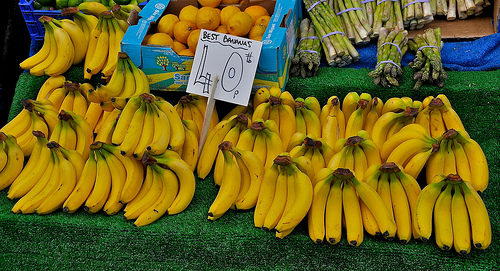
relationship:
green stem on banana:
[457, 180, 471, 194] [458, 180, 491, 250]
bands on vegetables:
[325, 29, 344, 35] [304, 4, 441, 83]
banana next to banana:
[248, 165, 293, 228] [248, 165, 273, 226]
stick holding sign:
[192, 77, 220, 157] [182, 26, 269, 111]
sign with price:
[182, 26, 269, 111] [195, 43, 242, 98]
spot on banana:
[152, 207, 159, 212] [134, 160, 178, 226]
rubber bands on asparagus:
[377, 41, 401, 50] [284, 0, 484, 85]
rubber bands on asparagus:
[372, 57, 404, 72] [284, 0, 484, 85]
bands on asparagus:
[321, 31, 346, 43] [284, 0, 484, 85]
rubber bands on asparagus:
[330, 7, 358, 15] [284, 0, 484, 85]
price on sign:
[199, 43, 243, 101] [189, 27, 269, 122]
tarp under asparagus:
[321, 31, 498, 71] [411, 26, 446, 88]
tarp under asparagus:
[321, 31, 498, 71] [369, 25, 409, 85]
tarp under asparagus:
[321, 31, 498, 71] [302, 0, 359, 68]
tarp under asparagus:
[321, 31, 498, 71] [290, 16, 320, 75]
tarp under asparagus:
[321, 31, 498, 71] [334, 0, 373, 43]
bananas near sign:
[2, 50, 192, 231] [182, 26, 269, 111]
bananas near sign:
[221, 82, 493, 254] [188, 23, 257, 106]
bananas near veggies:
[0, 42, 218, 228] [300, 4, 467, 89]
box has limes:
[18, 1, 88, 42] [35, 1, 75, 10]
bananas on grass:
[197, 87, 493, 254] [4, 204, 498, 270]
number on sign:
[194, 43, 244, 98] [182, 26, 269, 111]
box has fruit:
[119, 0, 309, 95] [196, 6, 220, 30]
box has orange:
[119, 0, 309, 95] [172, 19, 193, 41]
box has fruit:
[119, 0, 309, 95] [227, 12, 254, 36]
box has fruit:
[119, 0, 309, 95] [147, 33, 174, 48]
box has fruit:
[119, 0, 309, 95] [244, 6, 269, 23]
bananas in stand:
[197, 87, 493, 254] [11, 14, 493, 269]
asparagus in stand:
[368, 26, 409, 88] [11, 14, 493, 269]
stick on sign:
[198, 74, 220, 158] [184, 27, 264, 107]